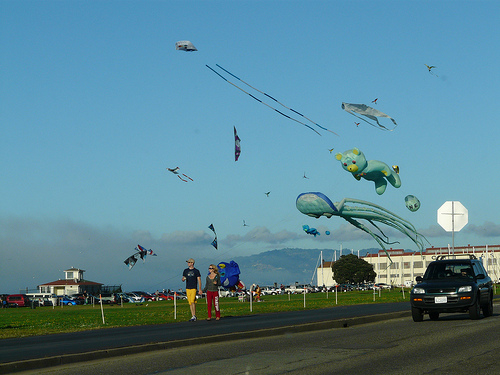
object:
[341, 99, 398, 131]
kite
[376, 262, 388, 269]
window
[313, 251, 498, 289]
building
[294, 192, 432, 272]
kite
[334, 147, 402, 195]
kite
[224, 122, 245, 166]
kite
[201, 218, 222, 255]
kite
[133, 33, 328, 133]
kite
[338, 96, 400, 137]
kite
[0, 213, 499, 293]
clouds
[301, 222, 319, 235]
kite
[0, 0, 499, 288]
sky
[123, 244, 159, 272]
kite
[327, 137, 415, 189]
kite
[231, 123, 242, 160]
kite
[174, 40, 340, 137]
kite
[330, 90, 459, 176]
kite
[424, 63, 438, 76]
kite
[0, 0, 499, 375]
air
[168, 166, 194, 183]
kite